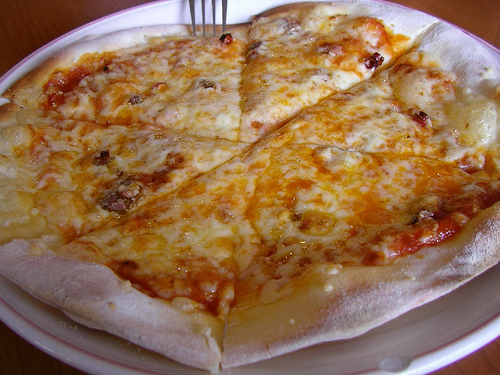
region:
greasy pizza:
[200, 128, 344, 258]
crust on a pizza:
[264, 248, 477, 341]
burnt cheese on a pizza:
[79, 130, 179, 245]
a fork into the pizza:
[184, 1, 251, 49]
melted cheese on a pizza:
[155, 43, 318, 246]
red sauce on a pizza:
[362, 185, 456, 278]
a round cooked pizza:
[3, 7, 478, 372]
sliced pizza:
[125, 82, 341, 261]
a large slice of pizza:
[210, 113, 458, 368]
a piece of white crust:
[11, 210, 204, 373]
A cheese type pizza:
[46, 43, 428, 325]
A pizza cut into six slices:
[40, 28, 440, 284]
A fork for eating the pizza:
[151, 3, 242, 43]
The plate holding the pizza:
[13, 302, 98, 357]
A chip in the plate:
[376, 353, 411, 373]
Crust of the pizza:
[233, 232, 473, 367]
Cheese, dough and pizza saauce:
[61, 70, 287, 275]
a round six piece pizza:
[25, 25, 460, 321]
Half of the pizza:
[236, 30, 429, 340]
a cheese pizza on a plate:
[22, 18, 469, 356]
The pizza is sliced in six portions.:
[370, 350, 416, 371]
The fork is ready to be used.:
[185, 0, 227, 37]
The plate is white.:
[2, 2, 497, 367]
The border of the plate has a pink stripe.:
[2, 320, 162, 370]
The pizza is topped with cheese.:
[185, 75, 240, 165]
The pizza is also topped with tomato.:
[400, 200, 470, 230]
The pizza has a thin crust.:
[3, 265, 491, 365]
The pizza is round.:
[6, 5, 496, 369]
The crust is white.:
[10, 247, 489, 363]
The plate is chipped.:
[375, 350, 420, 371]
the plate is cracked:
[373, 360, 406, 367]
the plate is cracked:
[364, 351, 399, 373]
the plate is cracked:
[385, 353, 397, 370]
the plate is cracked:
[379, 355, 391, 371]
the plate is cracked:
[379, 358, 390, 364]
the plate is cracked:
[387, 348, 401, 371]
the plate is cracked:
[384, 360, 391, 373]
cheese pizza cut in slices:
[138, 146, 415, 323]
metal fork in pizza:
[183, 1, 291, 75]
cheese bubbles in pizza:
[89, 159, 144, 218]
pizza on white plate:
[3, 18, 486, 363]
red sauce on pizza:
[145, 266, 272, 336]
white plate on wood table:
[425, 318, 499, 368]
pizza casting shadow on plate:
[384, 263, 494, 355]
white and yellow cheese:
[213, 93, 398, 229]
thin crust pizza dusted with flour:
[223, 253, 409, 368]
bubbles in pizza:
[388, 54, 498, 165]